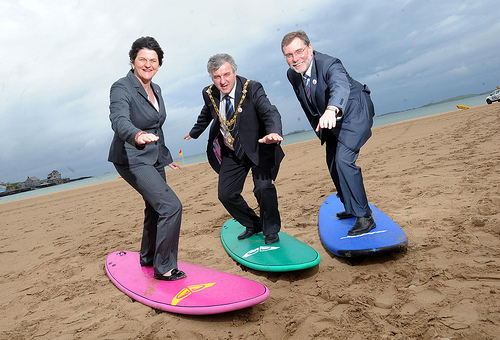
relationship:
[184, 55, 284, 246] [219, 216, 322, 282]
man on surfboard man standing surfboard is green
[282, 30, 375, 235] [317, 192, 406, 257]
man has beard man standing surfboard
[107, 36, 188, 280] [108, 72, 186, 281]
woman wearing suit suit grey suit is for business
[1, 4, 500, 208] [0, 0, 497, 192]
clouds in sky sky blue clouds in sky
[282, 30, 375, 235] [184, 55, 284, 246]
man has beard man wearing suit man in suit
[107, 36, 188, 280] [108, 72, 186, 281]
woman in suit woman wearing suit suit is for business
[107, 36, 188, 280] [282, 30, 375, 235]
suit is grey suit color grey man has beard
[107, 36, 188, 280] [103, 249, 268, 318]
woman on surfboard surfboard pink surfboard in sand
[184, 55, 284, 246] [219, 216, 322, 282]
man on surfboard surfboard green surboard in sand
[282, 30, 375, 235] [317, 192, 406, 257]
man has beard surfboard blue surfboard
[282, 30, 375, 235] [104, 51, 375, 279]
man has beard people in suits suits for business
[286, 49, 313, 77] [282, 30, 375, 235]
man has beard beard grey man has beard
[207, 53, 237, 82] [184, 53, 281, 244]
hair is grey man has hair man on surfboard